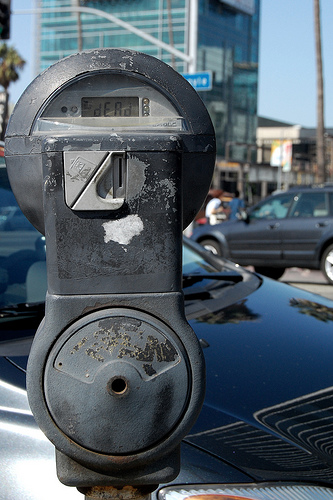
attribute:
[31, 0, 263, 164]
building — tall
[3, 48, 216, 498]
meter — gray , parking meter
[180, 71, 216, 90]
street sign — blue, white